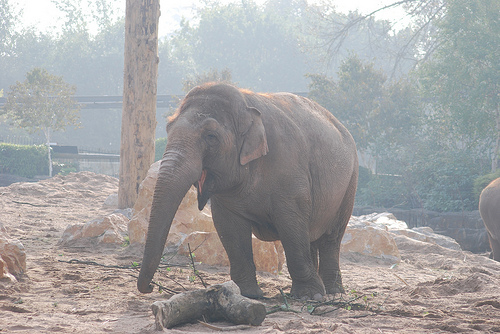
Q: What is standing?
A: Animal.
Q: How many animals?
A: Two.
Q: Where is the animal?
A: On dirt.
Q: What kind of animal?
A: Elephant.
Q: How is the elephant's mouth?
A: Open.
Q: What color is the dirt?
A: Tan.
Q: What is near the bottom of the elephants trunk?
A: Log.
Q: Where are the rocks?
A: Behind elephant.